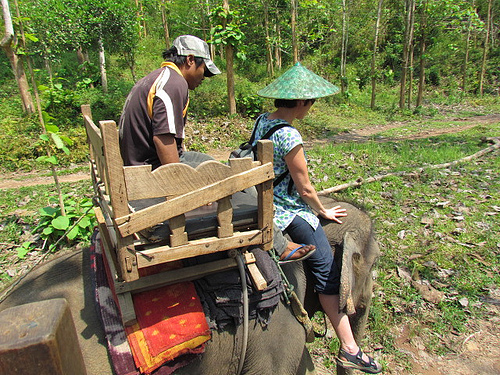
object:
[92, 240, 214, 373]
blanket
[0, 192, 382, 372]
elephant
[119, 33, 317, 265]
man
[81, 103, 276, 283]
seat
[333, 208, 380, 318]
head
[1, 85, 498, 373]
grass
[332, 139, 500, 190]
log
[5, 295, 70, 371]
post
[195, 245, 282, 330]
blanket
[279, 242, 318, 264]
sandal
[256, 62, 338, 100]
green hat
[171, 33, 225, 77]
baseball cap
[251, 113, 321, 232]
top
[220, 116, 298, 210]
backpack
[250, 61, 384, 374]
person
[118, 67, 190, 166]
shirt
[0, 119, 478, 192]
path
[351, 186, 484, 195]
ground